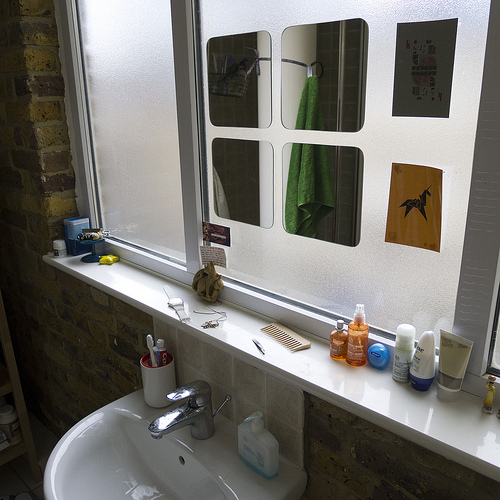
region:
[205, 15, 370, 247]
four bathroom mirrors on the wall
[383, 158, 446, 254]
yellow paper with black unicorn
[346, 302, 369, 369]
orange spray bottle on the counter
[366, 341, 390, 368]
blue circular container next to the orange spray bottle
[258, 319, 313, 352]
large brown comb on the counter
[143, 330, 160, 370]
white toothbrush in the cup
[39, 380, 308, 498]
white sink in the bathroom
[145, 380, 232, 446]
silver faucet in the sink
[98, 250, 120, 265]
yellow star on the counter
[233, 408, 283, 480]
white and blue container on the sink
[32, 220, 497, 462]
long and wide shelf in bathroom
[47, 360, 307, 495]
small and shiny white sink with faucet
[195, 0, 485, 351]
mirrored squares on frosted glass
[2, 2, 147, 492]
old bricks in stone wall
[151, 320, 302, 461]
beige and white tiled backsplash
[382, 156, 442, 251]
image of unicorn attached to glass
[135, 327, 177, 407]
white cup with toothbrush and toothpaste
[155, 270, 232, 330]
wristwatch and chained necklace with charms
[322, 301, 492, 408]
row of toiletries on back of shelf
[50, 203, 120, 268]
containers and knickknacks in corner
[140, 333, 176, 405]
container with toothbrush and toothpaste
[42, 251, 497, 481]
white shelf with bathroom items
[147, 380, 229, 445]
silver, metal faucet for sink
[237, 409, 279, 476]
almost empty soap bottle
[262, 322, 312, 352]
a light brown comb on the shelf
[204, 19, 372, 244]
four piece mirror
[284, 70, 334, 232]
reflection of green bath towek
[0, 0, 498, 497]
wall made of bricks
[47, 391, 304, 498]
shiny, white bathroom sink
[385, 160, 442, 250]
orange picture of horse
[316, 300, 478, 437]
items next to window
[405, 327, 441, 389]
bottle next to window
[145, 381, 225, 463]
faucet on the sink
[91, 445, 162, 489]
white sink in photo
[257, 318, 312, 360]
comb above the sink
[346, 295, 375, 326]
top of the bottle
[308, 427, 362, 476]
wall behind the sink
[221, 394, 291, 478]
soap next to sink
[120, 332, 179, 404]
cup next to faucet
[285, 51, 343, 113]
reflection of a green towel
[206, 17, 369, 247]
Mirrors on the wall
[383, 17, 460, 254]
Pictures on the wall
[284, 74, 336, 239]
Towel in the mirrors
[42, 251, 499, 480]
White counter on the wall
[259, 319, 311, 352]
Comb on the counter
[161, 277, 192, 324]
Watch on the counter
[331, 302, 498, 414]
Toiletries on the counter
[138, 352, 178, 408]
Cup on the sink counter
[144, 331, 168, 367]
Toothbrush and toothpaste in the cup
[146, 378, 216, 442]
Faucet over the sink